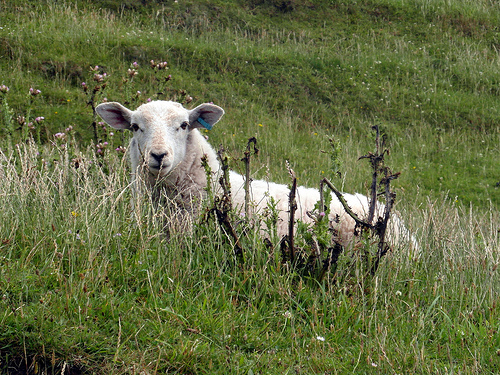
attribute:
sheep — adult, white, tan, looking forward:
[78, 85, 427, 271]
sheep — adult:
[98, 100, 419, 282]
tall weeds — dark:
[15, 139, 495, 309]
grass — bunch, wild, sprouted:
[2, 2, 496, 373]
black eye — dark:
[179, 118, 189, 132]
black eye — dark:
[129, 122, 138, 137]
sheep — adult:
[84, 92, 423, 259]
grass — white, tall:
[0, 130, 201, 303]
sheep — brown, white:
[88, 95, 429, 290]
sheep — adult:
[103, 103, 416, 257]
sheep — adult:
[56, 65, 466, 310]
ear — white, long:
[92, 97, 127, 130]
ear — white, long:
[189, 91, 226, 132]